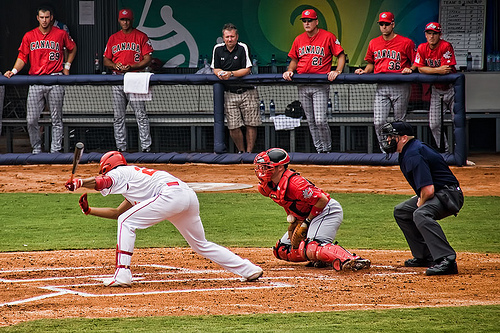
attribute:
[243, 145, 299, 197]
head — person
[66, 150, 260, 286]
player — baseball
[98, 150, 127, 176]
head — person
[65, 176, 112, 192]
arm — person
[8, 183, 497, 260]
field — baseball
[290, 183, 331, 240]
arm — person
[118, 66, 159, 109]
towel — white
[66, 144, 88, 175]
bat — baseball bat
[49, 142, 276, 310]
man — swinging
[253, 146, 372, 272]
catcher — baseball catcher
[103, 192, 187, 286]
leg — person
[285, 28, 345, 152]
uniform — baseball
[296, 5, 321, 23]
cap — red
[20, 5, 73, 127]
player — standing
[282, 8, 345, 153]
man — wearing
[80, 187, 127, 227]
arm — person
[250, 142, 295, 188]
mask — red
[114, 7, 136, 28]
cap — red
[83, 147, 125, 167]
helmet — red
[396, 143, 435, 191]
shirt — black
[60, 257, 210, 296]
base — home